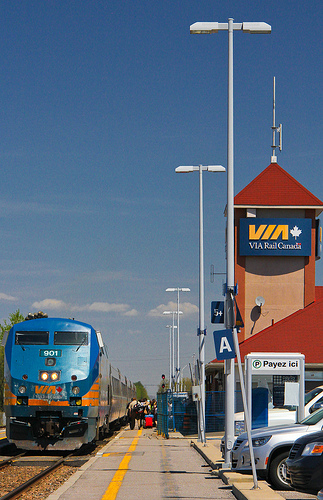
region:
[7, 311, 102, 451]
Blue front of passenger train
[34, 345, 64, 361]
Train number in white writing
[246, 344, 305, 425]
Box for pay parking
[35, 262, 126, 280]
Section of blue sky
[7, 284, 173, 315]
A few white clouds in blue sky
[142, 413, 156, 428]
A red roller suitcase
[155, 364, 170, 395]
Railroad signal lights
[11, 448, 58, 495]
Metal railroad tracks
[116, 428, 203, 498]
Concrete railway platform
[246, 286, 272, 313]
Wall-mounted satellite dish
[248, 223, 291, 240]
Large orange VIA letters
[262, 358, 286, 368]
The word Payez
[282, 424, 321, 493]
Very front of a black vehicle.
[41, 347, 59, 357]
White number 901 on a blue train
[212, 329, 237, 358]
Blue sign with an A on it.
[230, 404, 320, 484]
Silver car next to a black vehicle.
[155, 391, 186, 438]
A blue gate off a walkway.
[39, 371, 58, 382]
Two illuminated headlights on the front of a train.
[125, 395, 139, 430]
A dark skinned policeman standing by the train.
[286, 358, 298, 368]
The letters ici.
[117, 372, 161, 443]
several people standing together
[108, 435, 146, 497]
a yellow line painted on a platform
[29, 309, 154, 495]
a large passenger train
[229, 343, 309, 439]
a silver phone booth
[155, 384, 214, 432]
a blue metal fence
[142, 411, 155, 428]
a red suit case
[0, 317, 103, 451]
blue, orange and silver train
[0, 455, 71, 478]
a set of train tracks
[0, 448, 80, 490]
gravel next to train tracks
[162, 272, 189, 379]
three tall street lamp poles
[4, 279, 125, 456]
A blue train on a track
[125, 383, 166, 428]
People standing next to a train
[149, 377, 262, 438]
A blue fence near a train track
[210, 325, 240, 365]
A sign with the letter A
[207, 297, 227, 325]
A sign with the number five and a plus sign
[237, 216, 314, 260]
A sign that says VIA Rail Canada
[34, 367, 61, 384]
Headlights on a train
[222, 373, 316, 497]
Cars parked near a train track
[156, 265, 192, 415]
Light poles in a row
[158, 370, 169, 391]
Red lights near a train track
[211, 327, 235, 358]
blue sign with white A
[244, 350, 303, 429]
phone booth that says Paez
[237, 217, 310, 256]
blue sign that says VIA in yellow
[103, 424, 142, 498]
yellow line on pavement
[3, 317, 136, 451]
train on the tracks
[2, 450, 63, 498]
metal train track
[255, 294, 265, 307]
small silver satellite dish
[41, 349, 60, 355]
numbers on train that say 901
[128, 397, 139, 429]
person in black pants and tan shirt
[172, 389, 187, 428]
blue phone booth